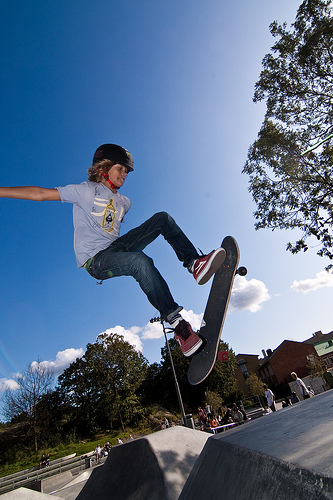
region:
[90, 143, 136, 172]
black helmet on head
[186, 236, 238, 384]
black and tan skate board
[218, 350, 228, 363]
red tire on skate board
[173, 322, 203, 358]
red and white sneaker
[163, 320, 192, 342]
red laces on sneaker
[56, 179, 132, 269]
grey cotton tee shirt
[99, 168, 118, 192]
red strap on helmet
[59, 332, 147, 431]
tree with green leaves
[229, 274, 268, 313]
white cloud in sky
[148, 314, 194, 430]
grey metal electrical pole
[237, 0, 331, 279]
this is a tree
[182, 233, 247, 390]
this is a skateboard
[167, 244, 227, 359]
these are his red sneakers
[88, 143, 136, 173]
this is his black hat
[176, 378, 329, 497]
this is a ramp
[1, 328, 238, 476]
these are more trees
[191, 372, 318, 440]
people are standing around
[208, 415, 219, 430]
a person wearing a orange shirt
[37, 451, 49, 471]
this is a person sitting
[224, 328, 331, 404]
these are some buildings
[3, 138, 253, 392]
skate boarder in mid jump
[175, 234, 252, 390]
black skate board with red and black wheels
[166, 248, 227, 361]
boys red and white skate shoes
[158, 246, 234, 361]
red shoes with black laces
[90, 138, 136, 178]
black sports safety helmet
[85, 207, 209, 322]
dark blue denim jeans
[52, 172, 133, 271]
boys light blue tee shirt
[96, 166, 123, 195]
red chin strap on safety helmet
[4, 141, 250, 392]
young boy on skate board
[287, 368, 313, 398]
person in white tee shirt walking in background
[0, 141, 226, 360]
Boy balancing in the air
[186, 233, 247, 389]
Black colored skateboard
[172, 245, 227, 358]
Red snickers with white lined sides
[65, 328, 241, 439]
Tall trees on the arena side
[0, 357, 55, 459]
Tree without leaves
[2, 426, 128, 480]
Grassy area behind the stands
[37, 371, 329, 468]
People in the background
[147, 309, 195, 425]
Tall mast with floodlights at the top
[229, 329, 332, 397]
Red brick buildings in the background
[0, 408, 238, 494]
Stands with long benches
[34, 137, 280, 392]
kid skateboarding in the air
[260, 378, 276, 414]
person with a white shirt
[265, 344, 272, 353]
chimney on the building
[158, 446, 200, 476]
shadow on the ramp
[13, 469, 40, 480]
bleachers with people sitting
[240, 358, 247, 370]
window on the building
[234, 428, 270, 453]
cement ramp for skateboarding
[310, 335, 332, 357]
green roof on the building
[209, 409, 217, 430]
person wearing a orange shirt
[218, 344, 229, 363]
red wheel on the skateboard